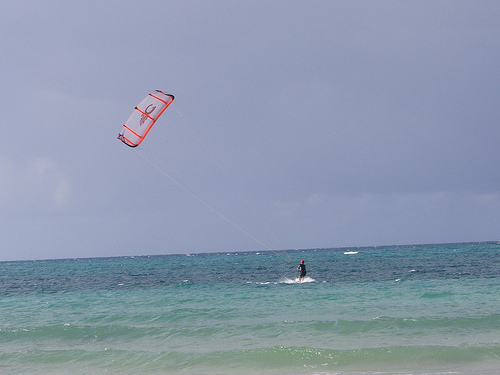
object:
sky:
[0, 0, 500, 206]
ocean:
[0, 260, 500, 374]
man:
[296, 259, 307, 281]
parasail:
[116, 89, 175, 149]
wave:
[325, 315, 480, 334]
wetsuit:
[297, 263, 306, 280]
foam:
[283, 276, 319, 285]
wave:
[64, 284, 125, 290]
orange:
[146, 114, 151, 117]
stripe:
[124, 125, 137, 135]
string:
[274, 247, 292, 262]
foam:
[343, 251, 359, 255]